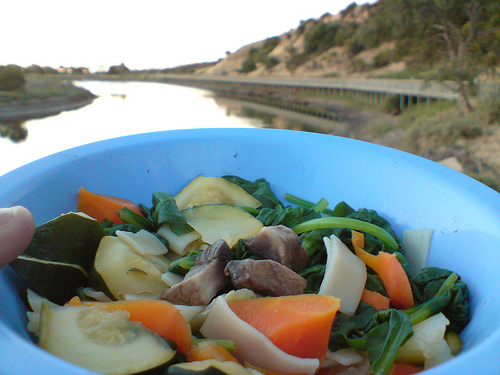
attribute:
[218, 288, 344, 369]
carrot — orange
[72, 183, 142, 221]
carrot — orange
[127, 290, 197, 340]
carrot — orange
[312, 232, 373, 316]
cheese — rectangular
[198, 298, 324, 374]
cheese — rectangular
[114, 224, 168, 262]
cheese — rectangluar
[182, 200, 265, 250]
cucumber — sliced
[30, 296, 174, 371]
cucumber — sliced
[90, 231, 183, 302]
cucumber — sliced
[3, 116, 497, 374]
bowl — blue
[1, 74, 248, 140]
river — long, curvey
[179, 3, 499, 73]
hill — large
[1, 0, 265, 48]
sky — bright gray